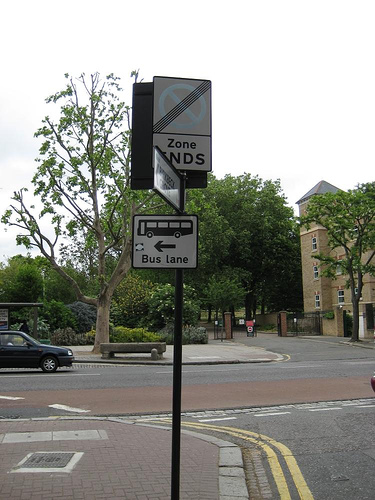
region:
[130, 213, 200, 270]
black and white sign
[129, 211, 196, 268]
black bus graphic on a white sign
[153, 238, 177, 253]
black left arrow graphic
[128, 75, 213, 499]
street signs posted on a black pole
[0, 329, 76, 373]
woman in a white shirt behind the wheel of a car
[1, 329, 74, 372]
woman in a black vehicle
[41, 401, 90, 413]
short thick white line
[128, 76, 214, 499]
four street signs on a black pole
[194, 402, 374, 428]
dash of white lines on a street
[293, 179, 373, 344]
tall tree in front of a brown building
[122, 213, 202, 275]
black and white sign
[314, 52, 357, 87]
white clouds in blue sky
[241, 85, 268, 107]
white clouds in blue sky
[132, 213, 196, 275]
the text is black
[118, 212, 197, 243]
picture of a bus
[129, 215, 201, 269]
sign indicates the bus lane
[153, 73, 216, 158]
sign says zone ends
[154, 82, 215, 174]
the text is black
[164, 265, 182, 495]
the pole is metal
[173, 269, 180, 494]
the metal pole is black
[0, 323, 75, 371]
the car is black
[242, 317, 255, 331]
red signs in the distance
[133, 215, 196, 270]
Square white sign with black border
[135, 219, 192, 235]
Picture of bus on sign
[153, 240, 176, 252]
Black arrow on sign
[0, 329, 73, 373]
Black car on road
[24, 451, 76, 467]
Metal cover in road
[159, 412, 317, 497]
Double yellow line on side of road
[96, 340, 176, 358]
Stone bench on road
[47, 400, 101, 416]
White line on road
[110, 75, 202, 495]
Street signs on pole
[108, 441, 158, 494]
Red bricks near road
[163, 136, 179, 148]
black letter on sign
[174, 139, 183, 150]
black letter on sign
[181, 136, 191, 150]
black letter on sign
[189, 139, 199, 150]
black letter on sign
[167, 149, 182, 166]
black letter on sign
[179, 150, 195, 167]
black letter on sign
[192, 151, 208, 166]
black letter on sign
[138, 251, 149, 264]
black letter on sign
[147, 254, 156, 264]
black letter on sign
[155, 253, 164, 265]
black letter on sign